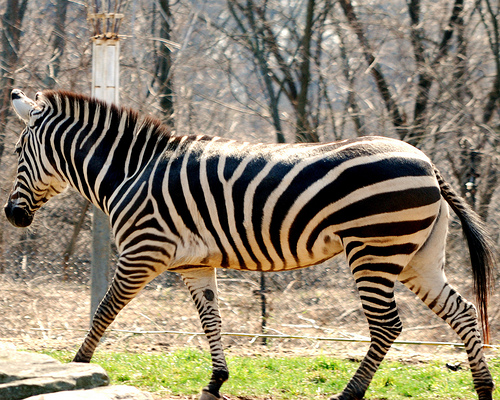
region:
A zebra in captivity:
[4, 82, 496, 399]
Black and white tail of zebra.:
[436, 169, 493, 343]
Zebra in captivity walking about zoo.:
[10, 90, 497, 399]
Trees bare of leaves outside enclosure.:
[235, 12, 497, 115]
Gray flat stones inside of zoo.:
[14, 342, 141, 399]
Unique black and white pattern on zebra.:
[170, 153, 384, 240]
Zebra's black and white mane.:
[46, 90, 170, 140]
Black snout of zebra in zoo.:
[3, 206, 30, 227]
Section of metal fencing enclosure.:
[9, 228, 91, 324]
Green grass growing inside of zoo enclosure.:
[250, 360, 334, 391]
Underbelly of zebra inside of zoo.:
[212, 242, 330, 270]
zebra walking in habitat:
[1, 71, 498, 398]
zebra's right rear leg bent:
[409, 225, 498, 397]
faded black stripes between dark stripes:
[338, 216, 406, 372]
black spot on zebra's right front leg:
[188, 280, 229, 306]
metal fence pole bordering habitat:
[75, 9, 115, 131]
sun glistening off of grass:
[1, 343, 458, 396]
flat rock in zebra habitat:
[2, 338, 113, 398]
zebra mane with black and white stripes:
[10, 75, 187, 157]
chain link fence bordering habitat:
[4, 238, 103, 361]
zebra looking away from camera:
[1, 76, 496, 395]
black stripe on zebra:
[113, 272, 149, 286]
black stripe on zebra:
[350, 262, 402, 276]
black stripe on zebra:
[355, 275, 394, 288]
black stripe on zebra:
[356, 285, 395, 300]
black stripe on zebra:
[360, 294, 395, 307]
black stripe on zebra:
[361, 303, 396, 313]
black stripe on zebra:
[364, 310, 398, 320]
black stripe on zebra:
[368, 317, 403, 328]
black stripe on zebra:
[371, 330, 394, 345]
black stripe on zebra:
[369, 342, 385, 357]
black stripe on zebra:
[348, 243, 416, 261]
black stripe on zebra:
[400, 274, 417, 286]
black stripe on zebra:
[408, 284, 415, 293]